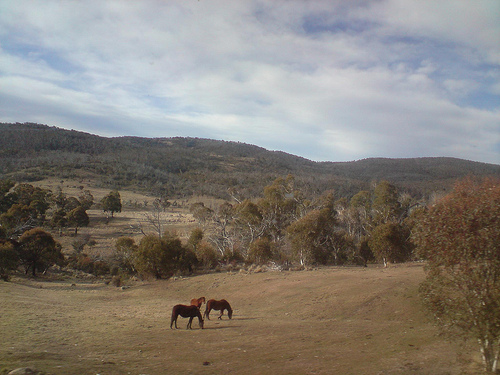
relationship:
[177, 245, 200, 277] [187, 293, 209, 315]
tree behind horse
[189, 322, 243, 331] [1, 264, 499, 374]
shadow on ground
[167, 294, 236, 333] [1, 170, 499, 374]
horses in large field